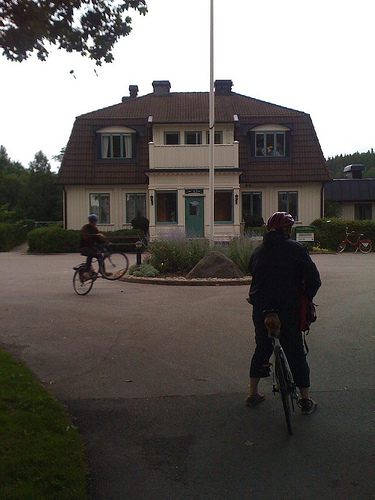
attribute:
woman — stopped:
[230, 197, 333, 422]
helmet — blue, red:
[259, 203, 300, 243]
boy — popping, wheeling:
[67, 205, 121, 283]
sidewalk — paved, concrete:
[15, 246, 350, 500]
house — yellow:
[49, 51, 330, 231]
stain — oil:
[147, 424, 205, 484]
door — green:
[180, 191, 212, 249]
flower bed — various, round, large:
[100, 230, 275, 280]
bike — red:
[318, 211, 370, 261]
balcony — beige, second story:
[145, 131, 245, 187]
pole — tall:
[205, 3, 230, 256]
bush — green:
[34, 223, 90, 260]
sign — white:
[135, 241, 154, 276]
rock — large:
[188, 252, 246, 288]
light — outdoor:
[230, 112, 246, 135]